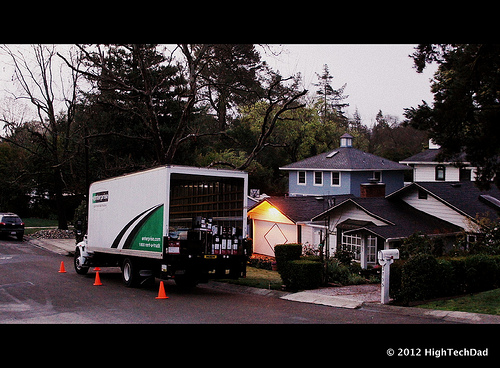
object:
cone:
[57, 260, 66, 273]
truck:
[73, 165, 248, 288]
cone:
[93, 270, 103, 285]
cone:
[93, 267, 101, 271]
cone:
[155, 281, 169, 299]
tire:
[74, 246, 91, 275]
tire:
[121, 256, 141, 287]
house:
[279, 132, 417, 196]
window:
[373, 170, 382, 182]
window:
[331, 171, 342, 187]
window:
[313, 171, 324, 187]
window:
[297, 170, 307, 185]